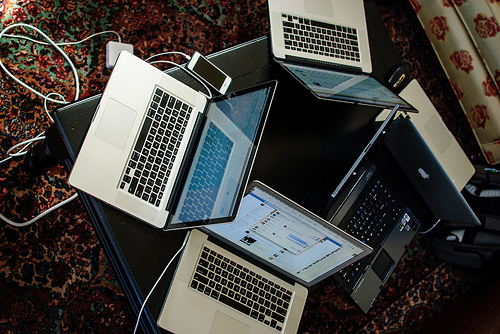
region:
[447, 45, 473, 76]
Red rose of a couch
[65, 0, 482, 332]
Five open laptops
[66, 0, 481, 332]
Five laptops on a table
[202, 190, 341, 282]
Facebook open on a computer screen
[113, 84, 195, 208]
Black keyboard of a laptop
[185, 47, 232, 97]
White shiny smartphone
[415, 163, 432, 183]
White Apple logo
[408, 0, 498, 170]
White couch with red roses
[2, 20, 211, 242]
White cables and cords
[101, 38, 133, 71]
Laptop power supply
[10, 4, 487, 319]
A bunch of computers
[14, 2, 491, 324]
These computers are laptops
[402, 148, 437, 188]
The laptops are made by Apple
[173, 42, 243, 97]
A cell phone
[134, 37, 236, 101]
The cell phone is plugged into the computer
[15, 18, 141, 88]
The computer charger is on the ground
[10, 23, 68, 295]
The floor is covered by a rug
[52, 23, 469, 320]
The computers are on a black table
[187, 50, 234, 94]
Phone on black table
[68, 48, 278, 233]
Large silver laptop is on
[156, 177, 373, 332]
Large silver laptop is on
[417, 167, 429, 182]
White Apple logo on laptop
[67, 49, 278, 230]
Laptop next to laptop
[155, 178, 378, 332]
Laptop next to laptop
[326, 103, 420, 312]
Laptop next to laptop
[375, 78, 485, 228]
Laptop next to laptop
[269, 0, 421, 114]
Laptop next to laptop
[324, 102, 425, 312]
Black laptop on black table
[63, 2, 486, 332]
Set of laptops on the table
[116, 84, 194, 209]
black keyboard of the laptop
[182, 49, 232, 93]
White cell phone on the table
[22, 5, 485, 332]
Black table on the floor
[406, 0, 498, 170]
Sofa in the back ground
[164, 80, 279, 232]
Screen of the laptop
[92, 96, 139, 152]
Touch pad of the laptop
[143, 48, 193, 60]
White wire connected to the cell phone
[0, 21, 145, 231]
White wires near the table on the floor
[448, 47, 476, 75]
Red flower design of the sofa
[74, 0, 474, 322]
the laptops on the coffee table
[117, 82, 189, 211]
the black keys on the laptop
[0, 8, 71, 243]
the white cords on the floor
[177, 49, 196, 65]
the plug in the phone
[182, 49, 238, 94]
the phone on the table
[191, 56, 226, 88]
the balck screen of the phone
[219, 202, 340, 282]
facebook open on the screen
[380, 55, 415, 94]
the black computer mouse on the table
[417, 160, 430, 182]
the logo on the back of the screen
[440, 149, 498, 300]
the balck backpack on the ground by the couch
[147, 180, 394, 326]
laptop with Facebook showing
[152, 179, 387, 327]
laptop with Facebook showing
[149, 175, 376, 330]
laptop with Facebook showing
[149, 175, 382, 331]
laptop with Facebook showing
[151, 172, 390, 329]
laptop with Facebook showing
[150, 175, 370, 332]
laptop with Facebook showing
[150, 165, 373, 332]
laptop with Facebook showing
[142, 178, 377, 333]
laptop with Facebook showing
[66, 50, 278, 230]
open silver laptop with black keys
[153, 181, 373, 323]
open silver laptop with black keys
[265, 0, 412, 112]
open silver laptop with black keys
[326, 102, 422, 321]
open silver laptop with black keys